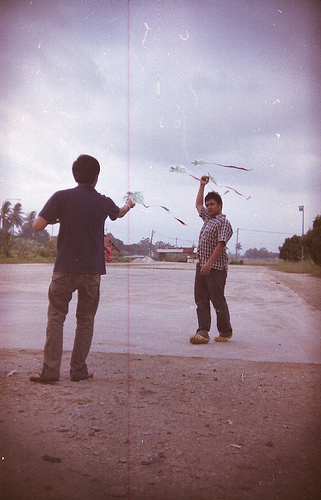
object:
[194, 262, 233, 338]
jeans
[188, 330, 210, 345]
shoe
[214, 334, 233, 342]
shoe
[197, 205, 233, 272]
shirt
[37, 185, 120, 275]
shirt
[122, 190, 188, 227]
kite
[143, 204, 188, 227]
tail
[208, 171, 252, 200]
tail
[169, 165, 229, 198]
kite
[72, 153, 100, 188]
head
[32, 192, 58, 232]
arm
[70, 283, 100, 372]
leg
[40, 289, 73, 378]
leg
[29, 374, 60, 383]
feet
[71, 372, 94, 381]
feet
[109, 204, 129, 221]
arm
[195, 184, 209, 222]
arm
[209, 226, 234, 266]
arm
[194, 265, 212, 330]
leg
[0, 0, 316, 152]
sky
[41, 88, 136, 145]
clouds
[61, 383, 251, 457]
ground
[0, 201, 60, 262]
trees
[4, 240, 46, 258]
leaves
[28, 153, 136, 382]
people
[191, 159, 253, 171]
kites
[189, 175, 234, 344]
man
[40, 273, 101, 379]
pants